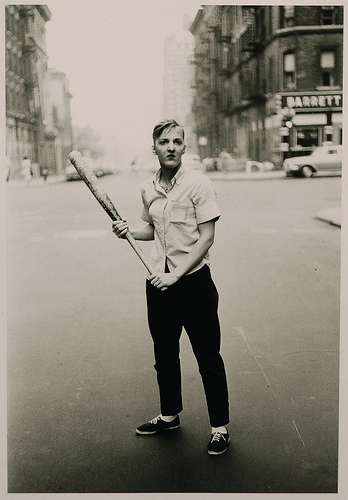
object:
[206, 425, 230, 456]
sneaker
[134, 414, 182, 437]
sneaker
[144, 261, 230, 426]
pants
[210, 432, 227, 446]
shoe laces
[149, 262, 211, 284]
shirt bottom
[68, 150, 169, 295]
baseball bat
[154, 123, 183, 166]
face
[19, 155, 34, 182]
woman walking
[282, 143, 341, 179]
car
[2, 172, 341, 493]
street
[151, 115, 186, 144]
hair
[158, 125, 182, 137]
forehead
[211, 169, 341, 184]
curb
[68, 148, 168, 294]
bat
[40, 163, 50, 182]
people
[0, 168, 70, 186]
sidewalk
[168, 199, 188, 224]
pocket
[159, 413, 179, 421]
sock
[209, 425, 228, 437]
sock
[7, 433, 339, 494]
shadow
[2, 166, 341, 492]
ground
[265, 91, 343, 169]
store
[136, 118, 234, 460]
person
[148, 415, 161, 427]
shoelace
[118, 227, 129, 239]
finger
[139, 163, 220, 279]
shirt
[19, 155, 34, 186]
woman